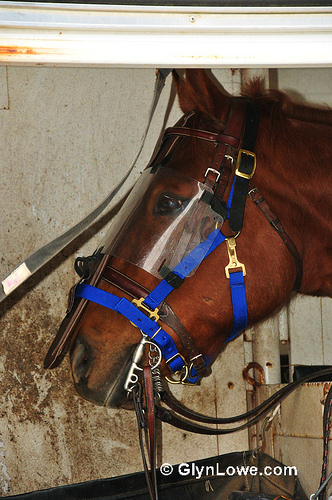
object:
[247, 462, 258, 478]
letter "e"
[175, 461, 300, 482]
word "glynlowe.com"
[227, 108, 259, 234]
reigns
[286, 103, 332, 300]
neck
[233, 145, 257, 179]
buckle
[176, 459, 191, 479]
g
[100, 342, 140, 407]
mouth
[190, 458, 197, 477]
letter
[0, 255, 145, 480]
dirt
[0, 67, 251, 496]
wall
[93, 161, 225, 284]
eye guard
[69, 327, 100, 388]
nose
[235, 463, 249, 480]
letter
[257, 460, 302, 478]
.com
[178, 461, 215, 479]
glyn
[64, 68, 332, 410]
horse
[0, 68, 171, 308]
leash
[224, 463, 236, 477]
letter o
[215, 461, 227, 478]
letter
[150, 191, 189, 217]
eye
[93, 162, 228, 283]
plastic